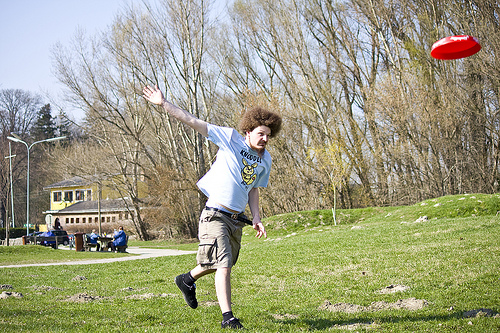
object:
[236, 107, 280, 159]
hair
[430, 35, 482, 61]
frisbee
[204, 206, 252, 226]
belt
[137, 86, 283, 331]
man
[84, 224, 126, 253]
people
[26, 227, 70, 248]
cars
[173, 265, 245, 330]
shoes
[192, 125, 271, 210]
shirt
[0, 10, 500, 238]
trees